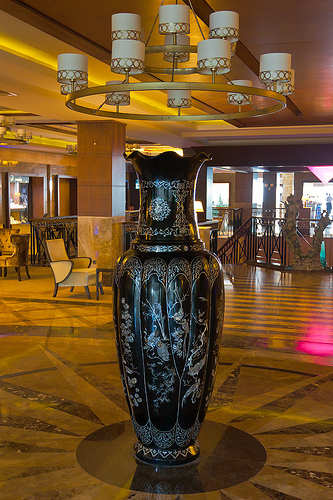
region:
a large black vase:
[107, 145, 229, 470]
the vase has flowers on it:
[109, 148, 225, 470]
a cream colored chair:
[41, 234, 106, 299]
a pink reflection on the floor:
[295, 319, 332, 366]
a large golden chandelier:
[53, 2, 295, 122]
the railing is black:
[211, 216, 291, 271]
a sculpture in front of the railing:
[278, 192, 332, 272]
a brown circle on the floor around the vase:
[73, 407, 268, 495]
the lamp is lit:
[191, 198, 204, 216]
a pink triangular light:
[306, 163, 332, 185]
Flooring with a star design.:
[0, 336, 329, 497]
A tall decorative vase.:
[110, 146, 222, 461]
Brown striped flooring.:
[218, 263, 323, 346]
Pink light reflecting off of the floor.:
[290, 318, 330, 359]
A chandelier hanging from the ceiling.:
[48, 0, 286, 115]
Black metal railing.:
[24, 212, 321, 265]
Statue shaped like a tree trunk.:
[275, 192, 325, 267]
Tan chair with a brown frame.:
[39, 236, 98, 293]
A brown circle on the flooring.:
[73, 416, 260, 487]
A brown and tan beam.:
[77, 119, 125, 284]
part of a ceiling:
[274, 0, 292, 19]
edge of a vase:
[174, 450, 190, 463]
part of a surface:
[216, 457, 239, 491]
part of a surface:
[281, 433, 294, 456]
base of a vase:
[156, 459, 172, 479]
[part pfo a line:
[259, 454, 274, 477]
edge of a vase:
[149, 442, 181, 482]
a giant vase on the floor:
[41, 138, 284, 496]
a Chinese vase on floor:
[102, 138, 234, 471]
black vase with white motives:
[102, 141, 234, 474]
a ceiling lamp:
[35, 2, 304, 135]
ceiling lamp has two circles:
[48, 3, 301, 137]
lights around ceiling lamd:
[42, 3, 303, 137]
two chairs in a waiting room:
[2, 201, 287, 360]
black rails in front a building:
[204, 203, 314, 272]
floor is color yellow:
[4, 268, 331, 499]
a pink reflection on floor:
[254, 270, 332, 382]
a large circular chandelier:
[50, 0, 292, 117]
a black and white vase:
[113, 141, 219, 459]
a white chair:
[41, 235, 100, 294]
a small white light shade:
[193, 34, 222, 66]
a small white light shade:
[53, 49, 82, 79]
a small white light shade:
[256, 51, 288, 79]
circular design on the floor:
[75, 414, 267, 493]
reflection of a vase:
[124, 456, 205, 498]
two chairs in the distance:
[0, 228, 30, 280]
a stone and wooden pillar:
[75, 123, 124, 267]